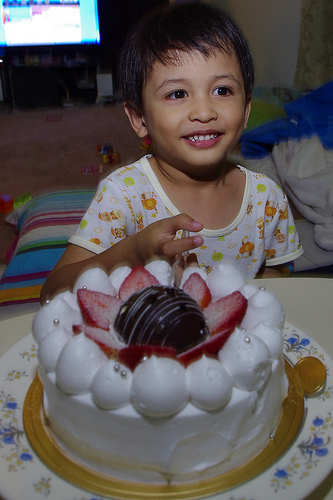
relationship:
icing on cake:
[31, 259, 288, 484] [33, 257, 292, 490]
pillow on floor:
[0, 189, 98, 308] [1, 103, 149, 249]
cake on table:
[33, 257, 292, 490] [279, 267, 332, 342]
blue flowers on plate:
[1, 324, 330, 492] [2, 294, 332, 496]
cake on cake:
[23, 257, 326, 499] [33, 257, 292, 490]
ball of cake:
[114, 283, 207, 344] [33, 257, 292, 490]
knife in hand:
[170, 226, 203, 304] [61, 198, 203, 264]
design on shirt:
[141, 197, 156, 210] [70, 152, 306, 284]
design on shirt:
[265, 203, 277, 217] [70, 152, 306, 284]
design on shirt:
[239, 239, 255, 255] [70, 152, 306, 284]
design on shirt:
[97, 208, 124, 222] [70, 152, 306, 284]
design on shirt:
[110, 225, 127, 241] [70, 152, 306, 284]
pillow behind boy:
[0, 189, 98, 308] [38, 5, 301, 304]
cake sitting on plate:
[33, 257, 292, 490] [0, 316, 331, 497]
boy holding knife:
[38, 5, 301, 304] [169, 227, 188, 279]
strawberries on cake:
[209, 291, 249, 320] [33, 257, 292, 490]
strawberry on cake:
[174, 326, 231, 366] [33, 257, 292, 490]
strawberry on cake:
[118, 343, 182, 373] [33, 257, 292, 490]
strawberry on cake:
[72, 323, 122, 359] [33, 257, 292, 490]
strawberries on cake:
[77, 288, 118, 330] [33, 257, 292, 490]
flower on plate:
[271, 462, 295, 480] [0, 316, 331, 497]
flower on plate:
[298, 432, 329, 461] [0, 316, 331, 497]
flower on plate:
[310, 413, 323, 427] [0, 316, 331, 497]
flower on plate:
[5, 393, 19, 410] [0, 316, 331, 497]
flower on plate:
[19, 447, 35, 462] [0, 316, 331, 497]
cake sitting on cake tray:
[33, 257, 292, 490] [0, 322, 333, 499]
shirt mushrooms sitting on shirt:
[137, 185, 157, 213] [64, 152, 306, 284]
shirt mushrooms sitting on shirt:
[232, 233, 253, 261] [64, 152, 306, 284]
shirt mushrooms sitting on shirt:
[263, 193, 276, 223] [64, 152, 306, 284]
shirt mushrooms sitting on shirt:
[277, 200, 290, 225] [64, 152, 306, 284]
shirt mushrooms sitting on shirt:
[264, 240, 278, 260] [64, 152, 306, 284]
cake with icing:
[23, 257, 326, 499] [93, 410, 237, 483]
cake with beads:
[23, 257, 326, 499] [112, 364, 127, 377]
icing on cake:
[31, 259, 288, 484] [23, 259, 312, 494]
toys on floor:
[77, 138, 125, 180] [2, 92, 331, 306]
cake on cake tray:
[23, 257, 326, 499] [15, 263, 325, 498]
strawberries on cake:
[66, 271, 243, 367] [36, 239, 285, 495]